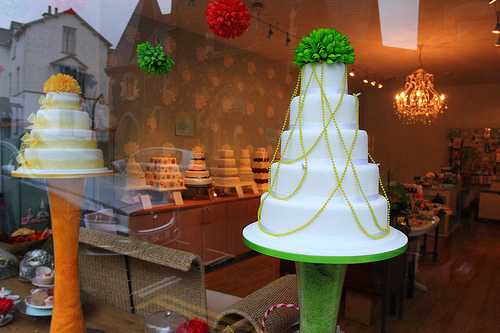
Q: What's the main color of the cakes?
A: White.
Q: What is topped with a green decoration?
A: The cake.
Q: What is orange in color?
A: The pedestal.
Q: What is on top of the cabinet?
A: A row of cakes.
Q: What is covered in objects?
A: The white table.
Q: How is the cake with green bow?
A: Five tier.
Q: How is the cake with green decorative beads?
A: Five tier.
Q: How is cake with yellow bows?
A: Four tier.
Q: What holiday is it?
A: Christmas.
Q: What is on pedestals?
A: Cakes.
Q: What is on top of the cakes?
A: Bows.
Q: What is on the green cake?
A: Beads.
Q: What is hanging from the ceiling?
A: Chandelier.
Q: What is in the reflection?
A: House.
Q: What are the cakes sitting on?
A: Tables.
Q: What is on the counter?
A: Cakes.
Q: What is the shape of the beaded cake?
A: Round.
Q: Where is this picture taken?
A: In a bakery.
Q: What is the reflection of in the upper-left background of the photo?
A: A house.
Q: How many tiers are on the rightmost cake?
A: Five.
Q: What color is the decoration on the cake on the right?
A: Green.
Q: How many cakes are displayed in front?
A: Two.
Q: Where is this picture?
A: A cake shop.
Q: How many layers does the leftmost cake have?
A: Four.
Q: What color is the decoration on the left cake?
A: Yellow.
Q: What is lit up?
A: The chandelier.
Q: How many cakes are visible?
A: Eight.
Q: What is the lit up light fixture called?
A: Chandelier.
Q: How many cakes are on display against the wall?
A: Six.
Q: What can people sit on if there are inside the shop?
A: Chairs.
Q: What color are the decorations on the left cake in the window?
A: Yellow.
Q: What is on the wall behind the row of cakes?
A: Wallpaper.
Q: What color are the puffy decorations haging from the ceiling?
A: Red and green.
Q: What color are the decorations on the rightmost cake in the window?
A: Green.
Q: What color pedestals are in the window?
A: Yellow and green.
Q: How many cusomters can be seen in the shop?
A: None.